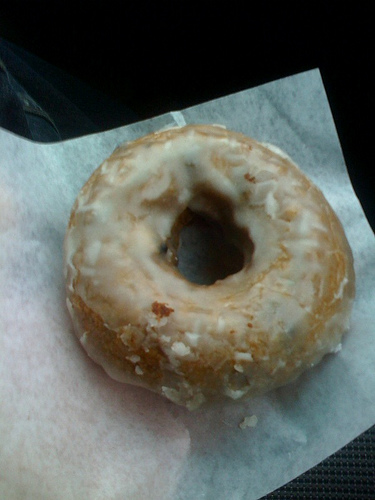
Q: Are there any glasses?
A: No, there are no glasses.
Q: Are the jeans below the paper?
A: Yes, the jeans are below the paper.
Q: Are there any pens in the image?
A: No, there are no pens.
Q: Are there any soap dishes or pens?
A: No, there are no pens or soap dishes.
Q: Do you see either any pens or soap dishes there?
A: No, there are no pens or soap dishes.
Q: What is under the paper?
A: The seat is under the paper.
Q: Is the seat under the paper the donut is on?
A: Yes, the seat is under the paper.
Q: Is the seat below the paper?
A: Yes, the seat is below the paper.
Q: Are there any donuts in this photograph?
A: Yes, there is a donut.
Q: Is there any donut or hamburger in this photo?
A: Yes, there is a donut.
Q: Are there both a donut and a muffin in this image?
A: No, there is a donut but no muffins.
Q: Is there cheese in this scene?
A: No, there is no cheese.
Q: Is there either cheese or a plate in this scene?
A: No, there are no cheese or plates.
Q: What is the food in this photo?
A: The food is a donut.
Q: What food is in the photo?
A: The food is a donut.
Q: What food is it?
A: The food is a donut.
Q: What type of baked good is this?
A: That is a donut.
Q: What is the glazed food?
A: The food is a donut.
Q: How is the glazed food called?
A: The food is a donut.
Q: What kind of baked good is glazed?
A: The baked good is a donut.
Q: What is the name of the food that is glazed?
A: The food is a donut.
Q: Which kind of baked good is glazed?
A: The baked good is a donut.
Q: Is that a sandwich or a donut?
A: That is a donut.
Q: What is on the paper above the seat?
A: The donut is on the paper.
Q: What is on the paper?
A: The donut is on the paper.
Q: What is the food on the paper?
A: The food is a donut.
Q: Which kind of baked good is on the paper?
A: The food is a donut.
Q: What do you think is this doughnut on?
A: The doughnut is on the paper.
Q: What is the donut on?
A: The doughnut is on the paper.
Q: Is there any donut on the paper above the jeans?
A: Yes, there is a donut on the paper.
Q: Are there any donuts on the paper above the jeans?
A: Yes, there is a donut on the paper.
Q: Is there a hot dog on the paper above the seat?
A: No, there is a donut on the paper.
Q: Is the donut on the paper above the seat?
A: Yes, the donut is on the paper.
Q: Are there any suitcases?
A: No, there are no suitcases.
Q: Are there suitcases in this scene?
A: No, there are no suitcases.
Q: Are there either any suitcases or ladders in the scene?
A: No, there are no suitcases or ladders.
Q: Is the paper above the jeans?
A: Yes, the paper is above the jeans.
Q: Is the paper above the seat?
A: Yes, the paper is above the seat.